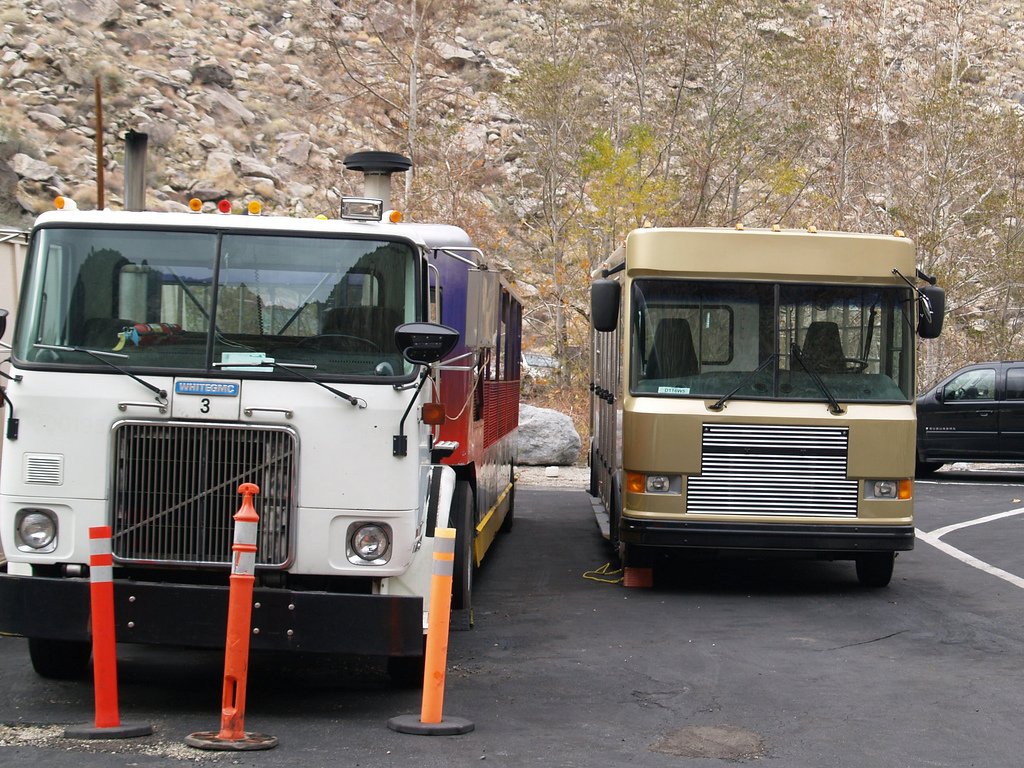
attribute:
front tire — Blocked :
[584, 518, 676, 601]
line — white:
[914, 532, 1022, 610]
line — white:
[923, 494, 1022, 542]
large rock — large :
[513, 383, 581, 470]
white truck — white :
[1, 202, 565, 694]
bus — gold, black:
[566, 216, 958, 600]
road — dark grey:
[663, 652, 962, 764]